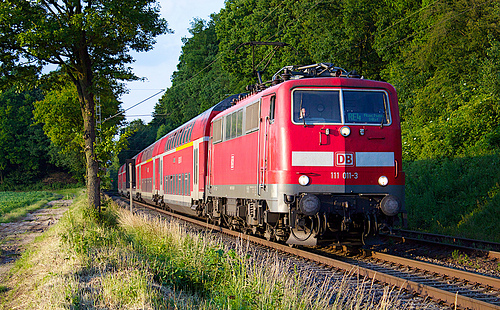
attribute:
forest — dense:
[113, 0, 499, 240]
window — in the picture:
[290, 88, 387, 123]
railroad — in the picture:
[327, 227, 487, 278]